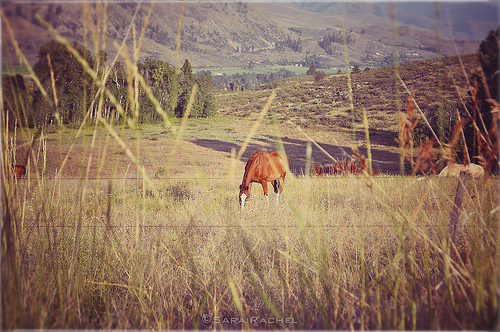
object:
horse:
[235, 148, 290, 211]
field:
[41, 115, 210, 251]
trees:
[176, 56, 200, 117]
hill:
[292, 49, 497, 130]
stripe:
[238, 193, 247, 209]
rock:
[435, 162, 486, 180]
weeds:
[67, 2, 151, 322]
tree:
[430, 94, 447, 149]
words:
[200, 313, 300, 325]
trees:
[347, 59, 363, 76]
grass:
[169, 233, 374, 288]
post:
[443, 169, 469, 265]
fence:
[332, 169, 500, 300]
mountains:
[118, 0, 298, 71]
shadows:
[190, 134, 416, 176]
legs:
[260, 180, 270, 205]